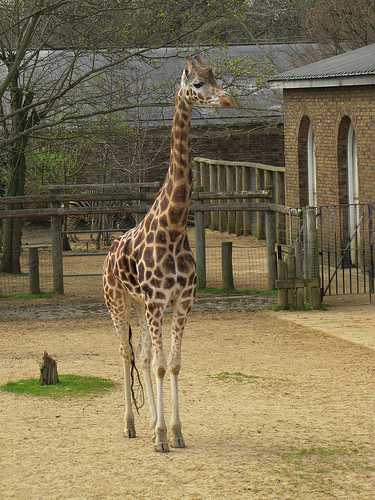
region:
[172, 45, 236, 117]
a giraffe with horns.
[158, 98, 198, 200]
a giraffe with a long neck.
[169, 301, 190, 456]
a left leg on a giraffe.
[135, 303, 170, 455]
a right leg on a giraffe.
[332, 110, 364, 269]
an arch on a brick building.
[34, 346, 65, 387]
a tree stump in grass.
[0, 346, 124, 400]
a patch of green grass.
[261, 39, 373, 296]
a one story brick building.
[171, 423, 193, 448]
a hoof on a giraffe.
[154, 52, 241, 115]
head of the giraffe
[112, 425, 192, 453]
hooves of the giraffe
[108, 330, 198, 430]
legs of the giraffe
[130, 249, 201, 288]
spots on the giraffe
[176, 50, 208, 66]
horns on the giraffe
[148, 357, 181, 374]
knees of the giraffe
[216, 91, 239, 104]
nose of the giraffe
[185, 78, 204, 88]
eye of the giraffe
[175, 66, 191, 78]
ear of the giraffe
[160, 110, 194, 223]
neck of the giraffe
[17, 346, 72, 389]
A small wood on the grass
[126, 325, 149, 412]
A long black tail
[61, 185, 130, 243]
There is a zebra on the background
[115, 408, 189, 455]
Four thin feet on the ground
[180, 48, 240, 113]
The giraffe has two small horns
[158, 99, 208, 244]
Th long neck of a giraffe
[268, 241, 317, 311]
Small wood fence on the background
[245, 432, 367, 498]
There are few grasses on the ground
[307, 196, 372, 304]
Small gate on the background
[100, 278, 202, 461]
Four long and thin legs of the giraffe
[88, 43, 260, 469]
a giraffe at a zoo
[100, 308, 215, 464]
the legs of a giraffe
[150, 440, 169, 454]
the hooves of a giraffe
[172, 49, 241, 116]
the head of a giraffe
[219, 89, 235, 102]
the nose of a giraffe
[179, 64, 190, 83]
the ear of a giraffe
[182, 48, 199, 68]
the horns of a giraffe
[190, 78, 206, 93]
the eye of a giraffe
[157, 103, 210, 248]
giraffe's neck is long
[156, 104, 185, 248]
giraffe's neck is long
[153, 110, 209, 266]
giraffe's neck is long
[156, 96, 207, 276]
giraffe's neck is long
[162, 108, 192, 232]
giraffe's neck is long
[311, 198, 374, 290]
the gate is closed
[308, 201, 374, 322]
the gate is closed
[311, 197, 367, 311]
the gate is closed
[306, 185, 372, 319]
the gate is closed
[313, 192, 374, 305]
the gate is closed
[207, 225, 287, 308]
short fence behind giraffe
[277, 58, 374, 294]
brown bricks on building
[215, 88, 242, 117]
giraffe has brown nose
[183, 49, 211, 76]
brown ossicles on giraffe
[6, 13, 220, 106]
thin branches on tree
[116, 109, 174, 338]
brown and tan spots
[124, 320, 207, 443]
giraffe has white legs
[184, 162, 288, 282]
brown and wooden posts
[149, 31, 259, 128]
head of the giraffe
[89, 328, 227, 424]
legs of the giraffe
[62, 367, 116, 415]
grass on the ground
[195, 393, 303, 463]
dirt on the ground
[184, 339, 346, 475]
grass and dirt on ground